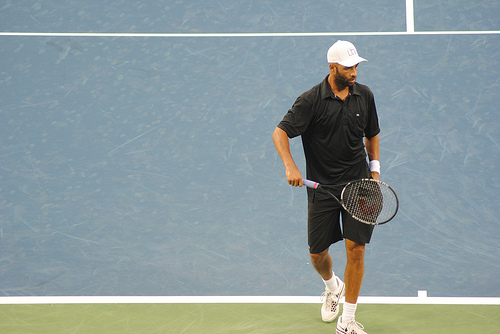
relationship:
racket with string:
[299, 176, 401, 224] [349, 183, 353, 212]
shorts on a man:
[306, 179, 379, 253] [271, 40, 400, 331]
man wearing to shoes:
[271, 40, 400, 331] [306, 276, 343, 320]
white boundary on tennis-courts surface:
[3, 5, 483, 313] [3, 5, 482, 330]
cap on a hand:
[322, 37, 366, 67] [283, 168, 304, 187]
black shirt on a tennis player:
[277, 80, 380, 189] [268, 37, 386, 332]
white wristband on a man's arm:
[368, 157, 382, 175] [366, 97, 381, 188]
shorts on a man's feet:
[306, 179, 379, 253] [272, 36, 383, 332]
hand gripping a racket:
[283, 168, 304, 187] [299, 176, 401, 224]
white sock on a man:
[339, 298, 359, 320] [271, 40, 400, 331]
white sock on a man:
[317, 272, 339, 292] [271, 40, 400, 331]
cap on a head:
[322, 37, 366, 67] [327, 39, 368, 86]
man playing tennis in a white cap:
[271, 40, 400, 331] [325, 36, 367, 67]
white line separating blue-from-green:
[0, 292, 500, 307] [15, 270, 265, 323]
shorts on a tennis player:
[306, 179, 379, 253] [268, 37, 386, 332]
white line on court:
[15, 292, 295, 307] [2, 2, 492, 332]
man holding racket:
[271, 40, 400, 331] [299, 176, 401, 224]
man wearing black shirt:
[271, 40, 400, 331] [277, 80, 380, 189]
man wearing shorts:
[271, 40, 400, 331] [298, 169, 372, 257]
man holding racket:
[271, 40, 400, 331] [291, 175, 402, 231]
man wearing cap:
[271, 40, 400, 331] [322, 37, 366, 67]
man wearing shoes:
[271, 40, 400, 331] [315, 273, 349, 324]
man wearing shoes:
[271, 40, 400, 331] [326, 314, 369, 333]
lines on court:
[2, 294, 498, 310] [2, 2, 492, 332]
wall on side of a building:
[17, 7, 484, 304] [18, 14, 481, 297]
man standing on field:
[271, 40, 400, 331] [8, 8, 481, 320]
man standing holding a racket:
[271, 40, 400, 331] [301, 163, 398, 226]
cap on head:
[322, 37, 366, 67] [326, 37, 368, 86]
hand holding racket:
[283, 168, 304, 187] [303, 170, 400, 224]